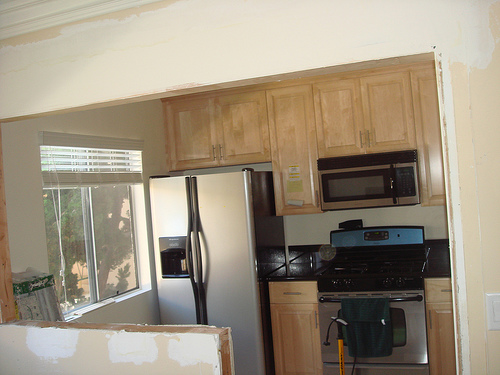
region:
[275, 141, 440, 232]
a black and silver microwave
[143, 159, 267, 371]
a silver refrigerator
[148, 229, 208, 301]
a ice and water maker on a fridge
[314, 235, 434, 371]
a silver and black oven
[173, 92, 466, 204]
brown wooden cabinets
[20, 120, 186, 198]
white shades on a window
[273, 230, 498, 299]
black countertops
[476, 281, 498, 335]
a white light switch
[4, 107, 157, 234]
white walls in a kitchen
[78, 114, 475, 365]
a kitchen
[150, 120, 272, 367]
FRIDGE WITH SILVER DOORS IN KITCHEN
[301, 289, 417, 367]
SILVER OVEN ON RIGHT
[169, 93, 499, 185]
WOODEN CABINETS IN KITCHEN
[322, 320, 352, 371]
YELLOW BICYCLE PUMP IN KITCHEN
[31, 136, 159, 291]
SQUARE WINDOW ON WALL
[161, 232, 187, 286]
BLACK ICE MAKER ON FRIDGE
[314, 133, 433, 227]
SILVER AND BLACK MICROWAVE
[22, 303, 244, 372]
DRY WALL ON LEFT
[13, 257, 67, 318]
OPEN BOX OF DRYWALL PLASTER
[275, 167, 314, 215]
SMALL SIGN ON WOOD CABINET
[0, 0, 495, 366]
a newly built ans furnished kitchen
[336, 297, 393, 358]
a dark green towel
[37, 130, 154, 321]
sliding window with white blinds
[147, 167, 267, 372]
silver stainless steel refrigerator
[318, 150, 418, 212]
a silver and black toaster oven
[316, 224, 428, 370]
a silver and black stove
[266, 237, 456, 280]
black counter top on each side of the stove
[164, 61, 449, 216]
wooden cabinets on the wall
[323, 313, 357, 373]
a yellow and black tire pump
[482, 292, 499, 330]
a white colored light switch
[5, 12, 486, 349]
Kitchen under renovation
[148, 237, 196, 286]
Refrigerator water dispenser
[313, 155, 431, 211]
Black and grey built-in microwave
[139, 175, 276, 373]
Silver and black double door refrigerator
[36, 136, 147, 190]
White window blinds drawn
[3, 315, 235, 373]
Stuccoed wooden partition being renovated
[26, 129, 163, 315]
Window with blinds drawn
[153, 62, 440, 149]
Tan wooden kitchen cabinets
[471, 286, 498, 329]
Light switch on wall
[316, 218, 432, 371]
Grey metallic closed stove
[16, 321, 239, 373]
fresh cut pass through section of kitchen wall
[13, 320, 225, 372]
places of patched drywall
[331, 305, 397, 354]
forest green kitchen towel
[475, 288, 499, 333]
light switch plate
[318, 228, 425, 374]
black and stainless steel range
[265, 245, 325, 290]
black grantie countertop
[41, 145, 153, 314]
sliding glass kitchen window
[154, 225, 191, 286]
ice maker in freezer door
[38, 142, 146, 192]
white mini blinds pulled up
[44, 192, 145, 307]
tree with green leaves outside window